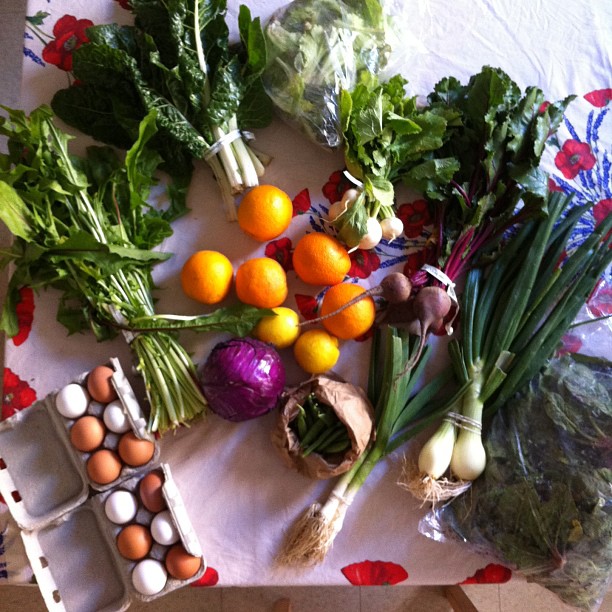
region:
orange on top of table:
[178, 244, 236, 306]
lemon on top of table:
[298, 329, 345, 372]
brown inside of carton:
[111, 524, 153, 557]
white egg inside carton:
[130, 564, 167, 595]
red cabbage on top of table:
[203, 335, 286, 421]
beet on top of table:
[409, 289, 455, 356]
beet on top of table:
[293, 269, 413, 326]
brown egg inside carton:
[70, 414, 105, 450]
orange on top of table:
[290, 229, 352, 286]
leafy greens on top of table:
[51, 0, 267, 222]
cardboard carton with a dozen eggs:
[1, 356, 203, 610]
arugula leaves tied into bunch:
[2, 103, 275, 443]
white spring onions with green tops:
[412, 190, 609, 505]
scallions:
[279, 329, 462, 573]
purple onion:
[195, 336, 285, 425]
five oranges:
[181, 185, 380, 339]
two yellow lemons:
[258, 305, 342, 373]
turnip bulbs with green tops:
[325, 63, 443, 252]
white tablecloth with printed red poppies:
[2, 31, 513, 589]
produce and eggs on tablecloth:
[1, 31, 605, 593]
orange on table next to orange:
[236, 184, 292, 243]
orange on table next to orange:
[178, 249, 230, 303]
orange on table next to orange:
[235, 256, 289, 310]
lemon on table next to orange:
[252, 306, 302, 348]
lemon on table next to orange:
[292, 330, 338, 375]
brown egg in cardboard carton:
[84, 366, 116, 405]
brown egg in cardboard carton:
[70, 415, 106, 451]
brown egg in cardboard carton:
[117, 431, 155, 469]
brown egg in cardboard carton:
[137, 472, 164, 514]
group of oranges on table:
[187, 163, 349, 323]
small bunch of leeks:
[410, 315, 506, 486]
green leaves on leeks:
[473, 209, 602, 354]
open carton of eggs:
[36, 361, 224, 611]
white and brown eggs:
[59, 350, 207, 598]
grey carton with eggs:
[0, 371, 99, 610]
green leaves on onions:
[19, 128, 199, 346]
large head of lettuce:
[265, 4, 417, 150]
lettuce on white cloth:
[276, 4, 526, 138]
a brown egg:
[117, 435, 160, 456]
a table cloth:
[207, 472, 255, 528]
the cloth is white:
[203, 483, 275, 517]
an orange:
[292, 243, 345, 277]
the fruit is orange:
[237, 190, 295, 238]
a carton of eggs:
[51, 383, 183, 582]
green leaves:
[36, 153, 123, 265]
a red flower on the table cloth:
[557, 137, 594, 177]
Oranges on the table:
[150, 211, 381, 396]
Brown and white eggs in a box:
[59, 465, 211, 590]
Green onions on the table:
[274, 325, 460, 581]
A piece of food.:
[305, 326, 354, 372]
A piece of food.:
[315, 285, 404, 340]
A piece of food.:
[287, 241, 342, 283]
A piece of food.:
[237, 252, 296, 308]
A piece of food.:
[260, 312, 294, 340]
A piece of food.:
[121, 430, 151, 456]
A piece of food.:
[98, 400, 136, 434]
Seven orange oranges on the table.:
[176, 183, 377, 375]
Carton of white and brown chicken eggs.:
[3, 355, 208, 609]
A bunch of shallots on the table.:
[412, 191, 610, 499]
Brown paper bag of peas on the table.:
[271, 375, 382, 482]